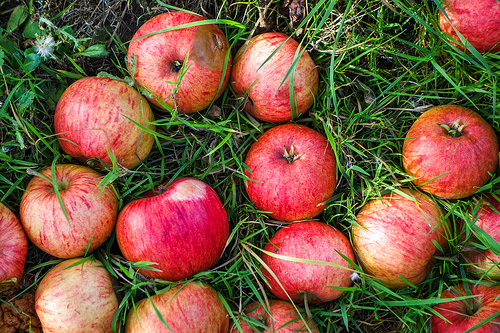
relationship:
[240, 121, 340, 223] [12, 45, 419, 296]
apple obscured by grass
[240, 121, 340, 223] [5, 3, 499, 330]
apple on ground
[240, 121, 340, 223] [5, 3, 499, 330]
apple are on ground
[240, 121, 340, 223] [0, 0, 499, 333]
apple are on green grass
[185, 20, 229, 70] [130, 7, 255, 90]
mark on fruit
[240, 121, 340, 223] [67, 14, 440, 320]
apple on ground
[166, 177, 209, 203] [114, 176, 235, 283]
patch on apple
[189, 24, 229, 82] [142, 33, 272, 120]
spot on apple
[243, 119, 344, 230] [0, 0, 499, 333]
apple laying in green grass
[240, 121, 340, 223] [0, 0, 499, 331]
apple on green grass